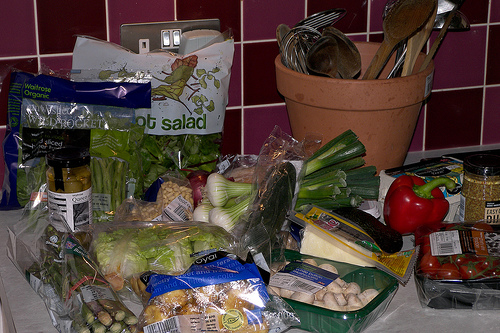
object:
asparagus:
[24, 223, 140, 333]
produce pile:
[0, 0, 500, 333]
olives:
[46, 164, 92, 193]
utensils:
[276, 0, 471, 79]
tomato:
[438, 263, 460, 280]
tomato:
[421, 252, 441, 275]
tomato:
[460, 259, 484, 279]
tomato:
[480, 256, 496, 273]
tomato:
[452, 253, 476, 267]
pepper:
[383, 175, 450, 235]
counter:
[0, 167, 500, 333]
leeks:
[191, 128, 381, 234]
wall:
[0, 0, 254, 137]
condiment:
[461, 153, 500, 230]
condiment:
[45, 146, 93, 233]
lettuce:
[91, 221, 237, 292]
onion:
[201, 173, 252, 208]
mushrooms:
[266, 258, 381, 312]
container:
[274, 40, 435, 177]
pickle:
[243, 161, 297, 254]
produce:
[0, 0, 499, 333]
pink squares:
[0, 0, 496, 159]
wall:
[426, 34, 498, 150]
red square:
[425, 86, 485, 151]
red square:
[428, 25, 487, 90]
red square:
[243, 106, 287, 154]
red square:
[243, 0, 304, 42]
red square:
[0, 2, 36, 58]